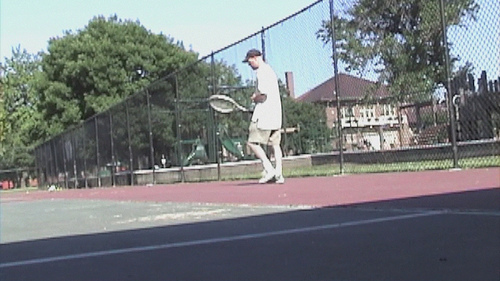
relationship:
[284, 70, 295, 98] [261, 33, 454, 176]
chimmney in house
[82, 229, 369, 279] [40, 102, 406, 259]
shade in tennis court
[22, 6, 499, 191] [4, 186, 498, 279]
fence in tennis court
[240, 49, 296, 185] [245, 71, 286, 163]
man wearing outfit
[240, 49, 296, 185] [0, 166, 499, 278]
man approaching court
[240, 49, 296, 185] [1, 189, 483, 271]
man approaching court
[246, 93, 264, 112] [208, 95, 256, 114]
hand holding racket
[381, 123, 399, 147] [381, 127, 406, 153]
door on garage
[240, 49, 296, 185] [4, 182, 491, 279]
man on court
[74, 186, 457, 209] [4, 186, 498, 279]
side lines on tennis court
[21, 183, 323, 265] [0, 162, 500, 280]
floor on court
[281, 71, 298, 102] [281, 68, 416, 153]
chimmney on house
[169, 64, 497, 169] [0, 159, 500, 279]
playground behind tennis court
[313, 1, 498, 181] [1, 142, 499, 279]
tree leftside of tennis court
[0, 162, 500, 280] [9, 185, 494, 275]
court in shade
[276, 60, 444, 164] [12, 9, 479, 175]
house in background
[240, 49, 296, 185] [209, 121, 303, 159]
man in shorts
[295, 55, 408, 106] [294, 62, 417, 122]
roof on house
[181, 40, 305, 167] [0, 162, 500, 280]
man on court